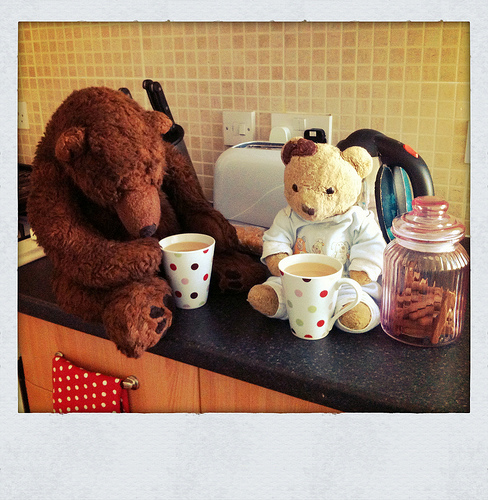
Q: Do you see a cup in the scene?
A: Yes, there is a cup.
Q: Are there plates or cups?
A: Yes, there is a cup.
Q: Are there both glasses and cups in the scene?
A: No, there is a cup but no glasses.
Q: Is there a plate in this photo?
A: No, there are no plates.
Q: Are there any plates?
A: No, there are no plates.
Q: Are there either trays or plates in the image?
A: No, there are no plates or trays.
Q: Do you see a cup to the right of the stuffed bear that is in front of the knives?
A: Yes, there is a cup to the right of the stuffed bear.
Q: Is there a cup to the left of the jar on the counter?
A: Yes, there is a cup to the left of the jar.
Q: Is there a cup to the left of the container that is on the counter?
A: Yes, there is a cup to the left of the jar.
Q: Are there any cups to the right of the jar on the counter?
A: No, the cup is to the left of the jar.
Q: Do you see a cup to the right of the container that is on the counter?
A: No, the cup is to the left of the jar.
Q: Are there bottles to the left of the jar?
A: No, there is a cup to the left of the jar.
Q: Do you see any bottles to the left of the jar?
A: No, there is a cup to the left of the jar.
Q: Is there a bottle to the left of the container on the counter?
A: No, there is a cup to the left of the jar.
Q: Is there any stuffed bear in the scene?
A: Yes, there is a stuffed bear.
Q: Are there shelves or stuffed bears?
A: Yes, there is a stuffed bear.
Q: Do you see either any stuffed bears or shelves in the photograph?
A: Yes, there is a stuffed bear.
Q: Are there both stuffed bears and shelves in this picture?
A: No, there is a stuffed bear but no shelves.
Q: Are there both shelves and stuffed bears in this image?
A: No, there is a stuffed bear but no shelves.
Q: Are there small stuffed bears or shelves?
A: Yes, there is a small stuffed bear.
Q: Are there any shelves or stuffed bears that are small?
A: Yes, the stuffed bear is small.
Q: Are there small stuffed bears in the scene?
A: Yes, there is a small stuffed bear.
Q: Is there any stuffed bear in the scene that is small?
A: Yes, there is a stuffed bear that is small.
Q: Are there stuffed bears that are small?
A: Yes, there is a stuffed bear that is small.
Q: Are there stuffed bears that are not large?
A: Yes, there is a small stuffed bear.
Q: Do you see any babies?
A: No, there are no babies.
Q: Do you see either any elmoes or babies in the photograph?
A: No, there are no babies or elmoes.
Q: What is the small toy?
A: The toy is a stuffed bear.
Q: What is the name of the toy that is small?
A: The toy is a stuffed bear.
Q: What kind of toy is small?
A: The toy is a stuffed bear.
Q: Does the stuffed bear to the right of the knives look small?
A: Yes, the stuffed bear is small.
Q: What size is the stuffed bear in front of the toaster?
A: The stuffed bear is small.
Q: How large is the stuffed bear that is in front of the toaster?
A: The stuffed bear is small.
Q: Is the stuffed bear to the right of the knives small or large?
A: The stuffed bear is small.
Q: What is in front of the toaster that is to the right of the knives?
A: The stuffed bear is in front of the toaster.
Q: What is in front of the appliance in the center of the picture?
A: The stuffed bear is in front of the toaster.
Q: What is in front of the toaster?
A: The stuffed bear is in front of the toaster.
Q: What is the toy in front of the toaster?
A: The toy is a stuffed bear.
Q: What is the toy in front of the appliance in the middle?
A: The toy is a stuffed bear.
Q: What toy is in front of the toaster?
A: The toy is a stuffed bear.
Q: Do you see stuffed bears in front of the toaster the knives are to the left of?
A: Yes, there is a stuffed bear in front of the toaster.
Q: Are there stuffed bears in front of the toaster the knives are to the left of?
A: Yes, there is a stuffed bear in front of the toaster.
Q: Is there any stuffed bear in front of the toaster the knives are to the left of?
A: Yes, there is a stuffed bear in front of the toaster.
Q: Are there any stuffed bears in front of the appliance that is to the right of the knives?
A: Yes, there is a stuffed bear in front of the toaster.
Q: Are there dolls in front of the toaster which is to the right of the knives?
A: No, there is a stuffed bear in front of the toaster.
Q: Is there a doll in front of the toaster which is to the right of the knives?
A: No, there is a stuffed bear in front of the toaster.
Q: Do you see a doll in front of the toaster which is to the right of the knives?
A: No, there is a stuffed bear in front of the toaster.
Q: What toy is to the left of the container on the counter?
A: The toy is a stuffed bear.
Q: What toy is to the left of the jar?
A: The toy is a stuffed bear.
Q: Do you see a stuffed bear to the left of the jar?
A: Yes, there is a stuffed bear to the left of the jar.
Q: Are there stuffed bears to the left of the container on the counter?
A: Yes, there is a stuffed bear to the left of the jar.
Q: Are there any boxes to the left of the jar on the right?
A: No, there is a stuffed bear to the left of the jar.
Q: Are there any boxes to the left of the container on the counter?
A: No, there is a stuffed bear to the left of the jar.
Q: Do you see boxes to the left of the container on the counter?
A: No, there is a stuffed bear to the left of the jar.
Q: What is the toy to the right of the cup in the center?
A: The toy is a stuffed bear.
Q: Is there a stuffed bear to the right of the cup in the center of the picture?
A: Yes, there is a stuffed bear to the right of the cup.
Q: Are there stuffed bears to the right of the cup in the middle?
A: Yes, there is a stuffed bear to the right of the cup.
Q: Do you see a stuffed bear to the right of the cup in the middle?
A: Yes, there is a stuffed bear to the right of the cup.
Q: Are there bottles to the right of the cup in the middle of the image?
A: No, there is a stuffed bear to the right of the cup.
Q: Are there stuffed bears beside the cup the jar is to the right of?
A: Yes, there is a stuffed bear beside the cup.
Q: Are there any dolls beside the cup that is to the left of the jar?
A: No, there is a stuffed bear beside the cup.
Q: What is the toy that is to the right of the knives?
A: The toy is a stuffed bear.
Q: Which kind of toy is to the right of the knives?
A: The toy is a stuffed bear.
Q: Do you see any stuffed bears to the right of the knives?
A: Yes, there is a stuffed bear to the right of the knives.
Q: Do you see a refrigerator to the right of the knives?
A: No, there is a stuffed bear to the right of the knives.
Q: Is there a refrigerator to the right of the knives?
A: No, there is a stuffed bear to the right of the knives.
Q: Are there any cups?
A: Yes, there is a cup.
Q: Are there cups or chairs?
A: Yes, there is a cup.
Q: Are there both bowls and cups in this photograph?
A: No, there is a cup but no bowls.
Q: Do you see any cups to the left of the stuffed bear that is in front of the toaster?
A: Yes, there is a cup to the left of the stuffed bear.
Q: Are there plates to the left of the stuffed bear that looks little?
A: No, there is a cup to the left of the stuffed bear.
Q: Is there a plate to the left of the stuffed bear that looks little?
A: No, there is a cup to the left of the stuffed bear.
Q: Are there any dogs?
A: No, there are no dogs.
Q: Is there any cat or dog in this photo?
A: No, there are no dogs or cats.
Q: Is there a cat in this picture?
A: No, there are no cats.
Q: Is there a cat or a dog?
A: No, there are no cats or dogs.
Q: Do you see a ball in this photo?
A: No, there are no balls.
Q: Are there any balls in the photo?
A: No, there are no balls.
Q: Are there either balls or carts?
A: No, there are no balls or carts.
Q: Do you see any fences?
A: No, there are no fences.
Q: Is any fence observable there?
A: No, there are no fences.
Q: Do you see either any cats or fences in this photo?
A: No, there are no fences or cats.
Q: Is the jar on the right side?
A: Yes, the jar is on the right of the image.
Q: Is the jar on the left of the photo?
A: No, the jar is on the right of the image.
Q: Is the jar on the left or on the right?
A: The jar is on the right of the image.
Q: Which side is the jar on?
A: The jar is on the right of the image.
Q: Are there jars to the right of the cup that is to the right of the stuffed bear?
A: Yes, there is a jar to the right of the cup.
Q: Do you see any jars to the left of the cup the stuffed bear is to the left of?
A: No, the jar is to the right of the cup.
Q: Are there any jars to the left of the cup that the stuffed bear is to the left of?
A: No, the jar is to the right of the cup.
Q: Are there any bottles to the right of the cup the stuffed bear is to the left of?
A: No, there is a jar to the right of the cup.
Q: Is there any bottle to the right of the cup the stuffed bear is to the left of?
A: No, there is a jar to the right of the cup.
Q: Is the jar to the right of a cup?
A: Yes, the jar is to the right of a cup.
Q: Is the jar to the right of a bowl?
A: No, the jar is to the right of a cup.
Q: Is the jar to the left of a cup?
A: No, the jar is to the right of a cup.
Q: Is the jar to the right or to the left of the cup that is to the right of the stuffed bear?
A: The jar is to the right of the cup.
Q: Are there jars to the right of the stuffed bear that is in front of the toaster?
A: Yes, there is a jar to the right of the stuffed bear.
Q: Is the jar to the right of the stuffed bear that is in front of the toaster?
A: Yes, the jar is to the right of the stuffed bear.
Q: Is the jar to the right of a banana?
A: No, the jar is to the right of the stuffed bear.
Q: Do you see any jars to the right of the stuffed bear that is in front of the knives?
A: Yes, there is a jar to the right of the stuffed bear.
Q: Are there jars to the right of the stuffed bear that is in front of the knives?
A: Yes, there is a jar to the right of the stuffed bear.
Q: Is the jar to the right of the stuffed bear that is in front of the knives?
A: Yes, the jar is to the right of the stuffed bear.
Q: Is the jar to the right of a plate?
A: No, the jar is to the right of the stuffed bear.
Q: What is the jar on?
A: The jar is on the counter.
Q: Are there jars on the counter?
A: Yes, there is a jar on the counter.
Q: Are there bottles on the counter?
A: No, there is a jar on the counter.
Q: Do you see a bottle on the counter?
A: No, there is a jar on the counter.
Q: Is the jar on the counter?
A: Yes, the jar is on the counter.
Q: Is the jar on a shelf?
A: No, the jar is on the counter.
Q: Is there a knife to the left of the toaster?
A: Yes, there are knives to the left of the toaster.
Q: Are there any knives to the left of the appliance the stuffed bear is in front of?
A: Yes, there are knives to the left of the toaster.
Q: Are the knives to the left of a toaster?
A: Yes, the knives are to the left of a toaster.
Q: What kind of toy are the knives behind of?
A: The knives are behind the stuffed bear.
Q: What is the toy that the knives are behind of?
A: The toy is a stuffed bear.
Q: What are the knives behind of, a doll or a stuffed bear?
A: The knives are behind a stuffed bear.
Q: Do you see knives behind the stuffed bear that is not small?
A: Yes, there are knives behind the stuffed bear.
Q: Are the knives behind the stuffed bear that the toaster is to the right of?
A: Yes, the knives are behind the stuffed bear.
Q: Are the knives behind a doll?
A: No, the knives are behind the stuffed bear.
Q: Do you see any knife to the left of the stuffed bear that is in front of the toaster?
A: Yes, there are knives to the left of the stuffed bear.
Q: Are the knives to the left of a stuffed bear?
A: Yes, the knives are to the left of a stuffed bear.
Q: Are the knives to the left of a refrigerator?
A: No, the knives are to the left of a stuffed bear.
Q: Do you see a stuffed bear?
A: Yes, there is a stuffed bear.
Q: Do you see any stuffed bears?
A: Yes, there is a stuffed bear.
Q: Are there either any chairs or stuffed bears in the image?
A: Yes, there is a stuffed bear.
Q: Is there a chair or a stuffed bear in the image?
A: Yes, there is a stuffed bear.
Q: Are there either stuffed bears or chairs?
A: Yes, there is a stuffed bear.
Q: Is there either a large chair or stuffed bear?
A: Yes, there is a large stuffed bear.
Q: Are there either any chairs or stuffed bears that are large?
A: Yes, the stuffed bear is large.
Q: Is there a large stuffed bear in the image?
A: Yes, there is a large stuffed bear.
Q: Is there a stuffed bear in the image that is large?
A: Yes, there is a stuffed bear that is large.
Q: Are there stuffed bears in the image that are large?
A: Yes, there is a stuffed bear that is large.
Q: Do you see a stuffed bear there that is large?
A: Yes, there is a stuffed bear that is large.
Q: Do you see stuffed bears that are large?
A: Yes, there is a stuffed bear that is large.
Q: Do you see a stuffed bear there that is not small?
A: Yes, there is a large stuffed bear.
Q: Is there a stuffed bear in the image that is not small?
A: Yes, there is a large stuffed bear.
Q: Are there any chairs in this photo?
A: No, there are no chairs.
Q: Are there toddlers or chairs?
A: No, there are no chairs or toddlers.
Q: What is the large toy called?
A: The toy is a stuffed bear.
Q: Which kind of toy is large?
A: The toy is a stuffed bear.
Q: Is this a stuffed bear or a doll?
A: This is a stuffed bear.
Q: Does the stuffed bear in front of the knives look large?
A: Yes, the stuffed bear is large.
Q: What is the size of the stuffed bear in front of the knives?
A: The stuffed bear is large.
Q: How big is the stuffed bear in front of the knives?
A: The stuffed bear is large.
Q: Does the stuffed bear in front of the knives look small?
A: No, the stuffed bear is large.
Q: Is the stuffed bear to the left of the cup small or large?
A: The stuffed bear is large.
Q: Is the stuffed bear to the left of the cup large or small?
A: The stuffed bear is large.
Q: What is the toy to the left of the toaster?
A: The toy is a stuffed bear.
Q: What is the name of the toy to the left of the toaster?
A: The toy is a stuffed bear.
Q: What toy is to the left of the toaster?
A: The toy is a stuffed bear.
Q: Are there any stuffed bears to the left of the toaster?
A: Yes, there is a stuffed bear to the left of the toaster.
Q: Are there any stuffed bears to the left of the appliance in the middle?
A: Yes, there is a stuffed bear to the left of the toaster.